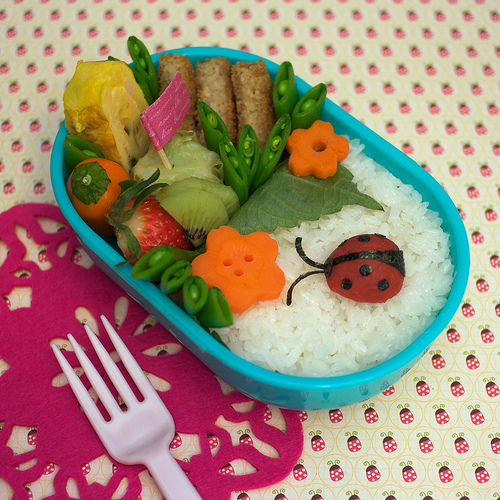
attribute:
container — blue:
[58, 49, 463, 384]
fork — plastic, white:
[37, 316, 221, 497]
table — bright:
[1, 3, 499, 500]